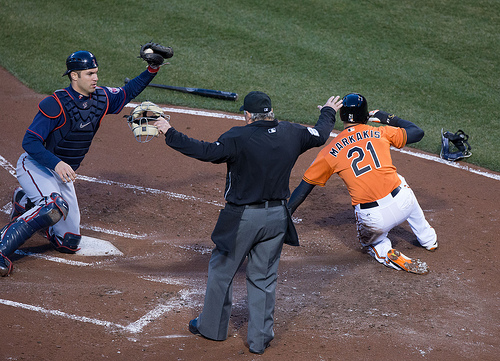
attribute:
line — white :
[396, 139, 499, 185]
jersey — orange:
[303, 122, 408, 206]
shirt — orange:
[299, 122, 407, 205]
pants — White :
[343, 181, 423, 273]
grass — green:
[4, 0, 496, 171]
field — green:
[2, 3, 498, 357]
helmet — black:
[61, 49, 105, 76]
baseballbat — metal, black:
[160, 84, 247, 114]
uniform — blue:
[33, 95, 91, 167]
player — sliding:
[288, 92, 438, 272]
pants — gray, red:
[13, 154, 80, 251]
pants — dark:
[198, 204, 289, 351]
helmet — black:
[333, 86, 372, 131]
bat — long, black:
[150, 80, 243, 105]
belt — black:
[353, 185, 403, 209]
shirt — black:
[313, 125, 418, 202]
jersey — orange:
[304, 119, 410, 201]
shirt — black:
[155, 104, 344, 211]